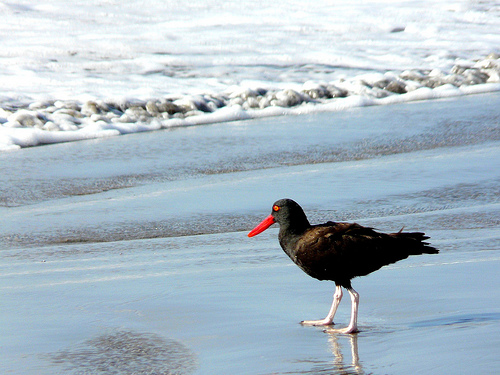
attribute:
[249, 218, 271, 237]
beak — red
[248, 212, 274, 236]
beak — red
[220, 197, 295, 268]
beak — bright, red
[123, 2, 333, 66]
water — rippled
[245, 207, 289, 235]
beak — red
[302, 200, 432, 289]
feathers — black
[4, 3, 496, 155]
wave — white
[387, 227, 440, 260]
tail feathers — long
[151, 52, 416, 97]
wave — white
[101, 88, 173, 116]
wave — white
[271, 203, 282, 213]
eye — red